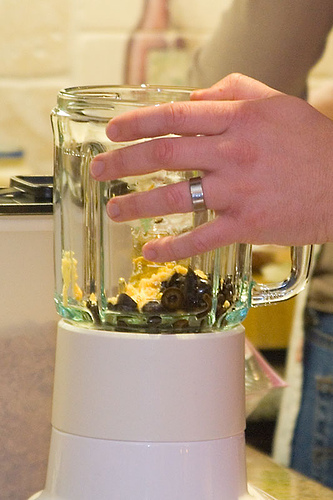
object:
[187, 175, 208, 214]
ring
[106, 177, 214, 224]
finger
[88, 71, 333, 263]
hand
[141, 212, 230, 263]
finger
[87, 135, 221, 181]
finger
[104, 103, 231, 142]
finger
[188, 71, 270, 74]
thumb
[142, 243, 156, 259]
fingernail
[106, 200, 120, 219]
fingernail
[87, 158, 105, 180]
fingernail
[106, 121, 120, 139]
fingernail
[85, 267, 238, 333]
olives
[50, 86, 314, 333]
blender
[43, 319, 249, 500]
bottom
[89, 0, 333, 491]
person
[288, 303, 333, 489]
jeans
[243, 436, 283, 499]
counter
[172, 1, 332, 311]
shirt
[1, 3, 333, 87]
wall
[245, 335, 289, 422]
bag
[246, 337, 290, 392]
zipper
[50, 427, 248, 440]
seam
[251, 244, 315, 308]
handle